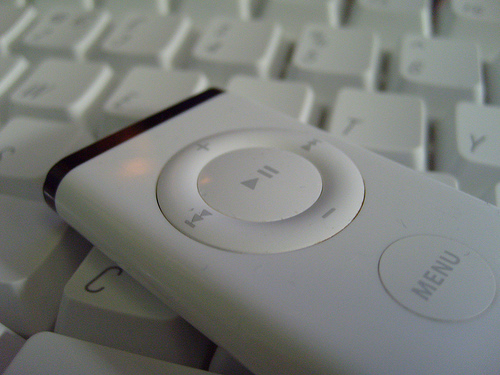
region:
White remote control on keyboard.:
[49, 83, 487, 373]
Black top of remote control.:
[35, 81, 232, 210]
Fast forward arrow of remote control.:
[290, 134, 325, 156]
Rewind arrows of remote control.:
[179, 203, 216, 239]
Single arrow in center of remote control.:
[235, 168, 259, 193]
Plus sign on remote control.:
[189, 140, 216, 153]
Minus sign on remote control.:
[302, 203, 346, 223]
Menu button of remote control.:
[372, 230, 496, 335]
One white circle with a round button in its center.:
[153, 122, 382, 259]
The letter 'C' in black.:
[57, 248, 191, 356]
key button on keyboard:
[96, 64, 215, 137]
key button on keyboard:
[1, 115, 95, 200]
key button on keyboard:
[8, 55, 117, 139]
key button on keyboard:
[226, 76, 325, 128]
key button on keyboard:
[323, 88, 430, 174]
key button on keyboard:
[435, 100, 498, 198]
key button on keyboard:
[1, 194, 93, 336]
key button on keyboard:
[52, 239, 212, 369]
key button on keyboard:
[2, 315, 28, 372]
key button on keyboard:
[2, 332, 224, 373]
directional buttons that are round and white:
[152, 115, 368, 264]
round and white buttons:
[157, 121, 372, 260]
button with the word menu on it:
[373, 218, 493, 341]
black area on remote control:
[41, 76, 228, 224]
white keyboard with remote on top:
[1, 2, 497, 373]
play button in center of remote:
[208, 147, 310, 219]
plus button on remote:
[171, 129, 223, 164]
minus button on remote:
[314, 195, 354, 237]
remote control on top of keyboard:
[39, 72, 497, 367]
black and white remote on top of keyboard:
[2, 3, 494, 370]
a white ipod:
[64, 84, 487, 372]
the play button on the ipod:
[218, 155, 312, 216]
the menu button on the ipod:
[383, 219, 479, 321]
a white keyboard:
[5, 57, 154, 351]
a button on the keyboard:
[73, 244, 158, 329]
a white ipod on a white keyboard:
[11, 53, 475, 363]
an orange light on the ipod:
[121, 147, 178, 195]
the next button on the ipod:
[298, 133, 328, 160]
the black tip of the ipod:
[23, 85, 260, 164]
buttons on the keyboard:
[13, 63, 465, 183]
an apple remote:
[74, 82, 349, 296]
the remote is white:
[91, 151, 448, 302]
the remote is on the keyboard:
[47, 78, 493, 359]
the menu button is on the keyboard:
[333, 236, 468, 303]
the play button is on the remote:
[153, 130, 423, 300]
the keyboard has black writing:
[90, 38, 300, 119]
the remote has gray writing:
[140, 149, 457, 373]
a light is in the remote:
[86, 155, 338, 204]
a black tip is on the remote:
[31, 93, 253, 146]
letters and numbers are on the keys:
[193, 23, 272, 81]